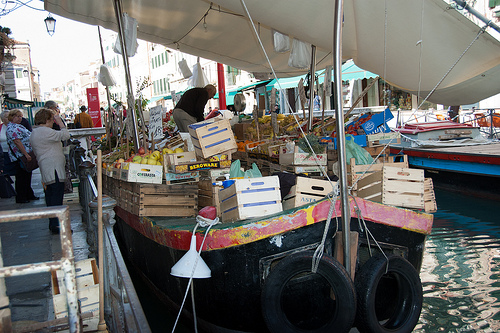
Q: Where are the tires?
A: Hanging on the boat.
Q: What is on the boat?
A: Wooden boxes.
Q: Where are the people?
A: On the dock.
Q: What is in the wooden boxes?
A: Fruit.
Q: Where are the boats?
A: Next to the dock.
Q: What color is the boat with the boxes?
A: Black and red.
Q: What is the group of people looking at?
A: The boat.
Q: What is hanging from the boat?
A: Two tires.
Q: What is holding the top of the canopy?
A: The string.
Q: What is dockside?
A: Produce market.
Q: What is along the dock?
A: Iron railing.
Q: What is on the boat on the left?
A: Fruit and a man.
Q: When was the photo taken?
A: Daytime.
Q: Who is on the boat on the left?
A: A man.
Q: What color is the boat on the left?
A: Black.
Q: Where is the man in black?
A: On the boat on the left.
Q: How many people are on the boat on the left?
A: One.